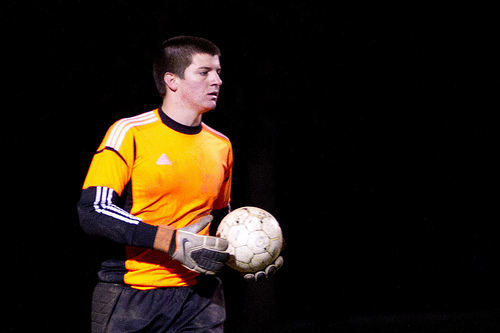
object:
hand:
[168, 215, 231, 276]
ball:
[215, 206, 284, 273]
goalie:
[74, 31, 285, 331]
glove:
[166, 214, 230, 276]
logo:
[156, 153, 171, 164]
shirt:
[78, 110, 235, 291]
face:
[188, 60, 223, 102]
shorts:
[89, 273, 229, 332]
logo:
[181, 236, 189, 259]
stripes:
[107, 109, 155, 149]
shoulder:
[101, 108, 160, 162]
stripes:
[94, 184, 141, 225]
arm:
[76, 122, 174, 255]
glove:
[242, 256, 284, 282]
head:
[150, 34, 222, 113]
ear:
[162, 69, 178, 92]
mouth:
[208, 90, 218, 98]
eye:
[197, 69, 211, 76]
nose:
[209, 70, 223, 86]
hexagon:
[227, 223, 250, 248]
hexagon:
[261, 213, 280, 239]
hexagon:
[234, 244, 253, 263]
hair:
[152, 34, 220, 96]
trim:
[156, 105, 207, 134]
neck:
[162, 102, 204, 124]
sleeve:
[77, 121, 158, 251]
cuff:
[135, 221, 161, 249]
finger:
[242, 273, 254, 282]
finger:
[255, 271, 266, 281]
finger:
[266, 264, 276, 277]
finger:
[274, 255, 285, 270]